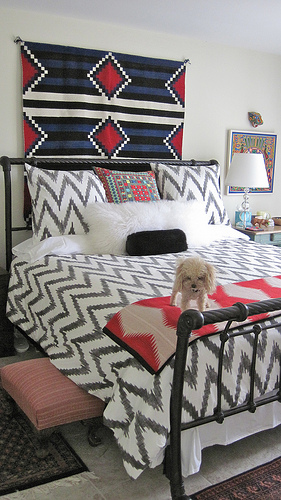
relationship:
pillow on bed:
[19, 160, 109, 245] [5, 160, 279, 494]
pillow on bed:
[150, 156, 226, 226] [5, 160, 279, 494]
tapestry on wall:
[18, 36, 190, 226] [1, 1, 280, 277]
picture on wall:
[226, 130, 277, 193] [0, 2, 278, 234]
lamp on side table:
[225, 149, 273, 228] [234, 222, 280, 241]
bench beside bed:
[0, 354, 107, 463] [25, 159, 280, 436]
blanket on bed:
[6, 238, 280, 477] [5, 160, 279, 494]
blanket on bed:
[102, 275, 279, 375] [5, 160, 279, 494]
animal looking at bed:
[169, 257, 217, 312] [5, 160, 279, 494]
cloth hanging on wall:
[14, 37, 189, 229] [1, 1, 280, 277]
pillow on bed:
[152, 160, 227, 226] [5, 160, 279, 494]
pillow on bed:
[93, 166, 156, 204] [5, 160, 279, 494]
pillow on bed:
[24, 160, 109, 245] [5, 160, 279, 494]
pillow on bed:
[124, 229, 188, 256] [5, 160, 279, 494]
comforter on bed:
[6, 238, 280, 479] [5, 160, 279, 494]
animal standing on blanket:
[169, 257, 217, 312] [102, 275, 279, 375]